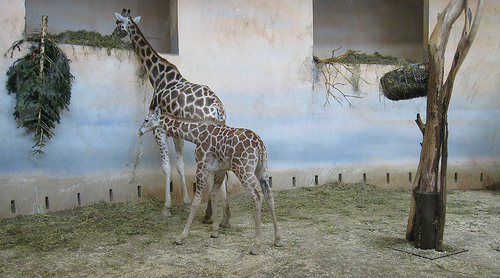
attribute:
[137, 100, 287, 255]
giraffe — BABY, standing, small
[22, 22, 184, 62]
shelf — high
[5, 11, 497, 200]
wall — old, faded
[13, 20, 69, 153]
branch — cut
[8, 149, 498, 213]
slits — some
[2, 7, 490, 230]
wall — one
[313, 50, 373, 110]
branches — hanging, bare, tree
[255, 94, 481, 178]
wall — painted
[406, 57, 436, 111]
basket — metal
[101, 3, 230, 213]
giraffe — eating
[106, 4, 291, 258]
giraffes — brown, white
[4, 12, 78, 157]
tree — green,  upside down, upside down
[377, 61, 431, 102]
basket — metal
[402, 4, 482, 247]
tree — dead, brown, dry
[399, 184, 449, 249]
cylinder — black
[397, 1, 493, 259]
tree — dry, dead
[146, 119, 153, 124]
eye — black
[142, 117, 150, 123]
eye — small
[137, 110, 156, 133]
face — white, brown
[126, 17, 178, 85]
neck — long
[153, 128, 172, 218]
leg — long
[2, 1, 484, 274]
habitat — artificial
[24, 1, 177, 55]
opening — square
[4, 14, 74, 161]
tree branch — hanging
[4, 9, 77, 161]
branch — tree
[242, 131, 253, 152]
spot — brown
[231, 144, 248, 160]
spot — brown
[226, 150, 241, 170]
spot — brown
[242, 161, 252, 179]
spot — brown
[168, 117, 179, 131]
spot — brown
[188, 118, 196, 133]
spot — brown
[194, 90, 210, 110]
spot — brown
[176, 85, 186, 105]
spot — brown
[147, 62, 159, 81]
spot — brown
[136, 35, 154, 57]
spot — brown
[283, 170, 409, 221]
pile — hay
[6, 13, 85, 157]
tree — small, pine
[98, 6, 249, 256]
giraffe — taller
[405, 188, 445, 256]
wood — piece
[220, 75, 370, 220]
paint — blue 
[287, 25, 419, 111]
branch — Dead 